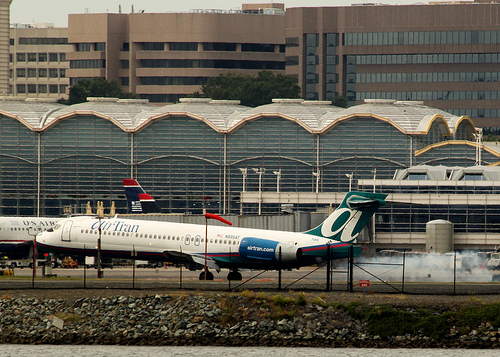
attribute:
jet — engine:
[42, 177, 390, 275]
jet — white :
[39, 188, 405, 287]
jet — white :
[0, 194, 96, 263]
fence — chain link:
[10, 242, 492, 299]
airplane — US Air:
[0, 177, 162, 258]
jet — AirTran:
[33, 188, 390, 280]